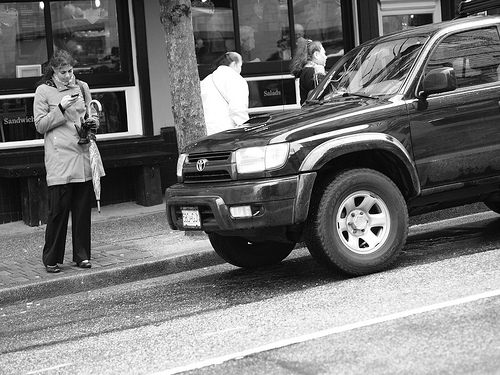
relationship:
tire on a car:
[312, 180, 408, 267] [158, 43, 474, 258]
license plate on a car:
[178, 204, 202, 228] [162, 32, 500, 275]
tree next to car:
[162, 0, 208, 244] [162, 32, 500, 275]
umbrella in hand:
[78, 92, 113, 216] [73, 114, 100, 137]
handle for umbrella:
[88, 96, 100, 125] [82, 97, 112, 214]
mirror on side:
[417, 63, 451, 97] [406, 12, 494, 195]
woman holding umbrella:
[35, 55, 103, 270] [70, 90, 114, 218]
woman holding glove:
[35, 55, 103, 270] [71, 114, 100, 148]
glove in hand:
[71, 114, 100, 148] [80, 115, 100, 135]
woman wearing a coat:
[35, 55, 102, 270] [35, 77, 104, 184]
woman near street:
[35, 55, 103, 270] [3, 206, 496, 373]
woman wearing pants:
[35, 55, 102, 270] [42, 183, 91, 263]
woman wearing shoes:
[35, 55, 103, 270] [42, 258, 91, 270]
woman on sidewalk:
[35, 55, 103, 270] [9, 228, 181, 277]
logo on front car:
[185, 154, 220, 179] [162, 32, 500, 275]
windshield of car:
[317, 36, 429, 103] [162, 32, 500, 275]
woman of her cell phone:
[35, 55, 103, 270] [69, 88, 79, 105]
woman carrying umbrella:
[35, 55, 103, 270] [78, 92, 118, 202]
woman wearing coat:
[35, 55, 103, 270] [293, 62, 329, 92]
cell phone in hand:
[69, 89, 84, 103] [58, 87, 80, 113]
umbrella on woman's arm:
[78, 92, 113, 216] [78, 86, 100, 136]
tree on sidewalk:
[162, 30, 212, 111] [21, 193, 262, 313]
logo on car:
[190, 154, 209, 174] [162, 32, 500, 275]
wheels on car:
[309, 161, 411, 281] [162, 32, 500, 275]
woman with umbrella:
[35, 55, 103, 270] [82, 97, 106, 217]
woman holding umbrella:
[35, 55, 103, 270] [82, 97, 106, 217]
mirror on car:
[417, 63, 457, 98] [188, 25, 485, 242]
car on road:
[162, 32, 500, 275] [2, 211, 498, 365]